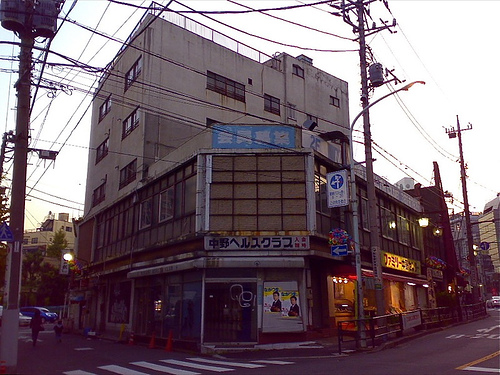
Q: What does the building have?
A: Many windows.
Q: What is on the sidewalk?
A: Light pole.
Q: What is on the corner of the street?
A: Store.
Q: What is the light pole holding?
A: Electrical wires.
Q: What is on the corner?
A: Old building.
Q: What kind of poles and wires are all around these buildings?
A: Electrical poles and wires.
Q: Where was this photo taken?
A: On a street corner.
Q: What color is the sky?
A: White.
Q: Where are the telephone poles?
A: In front of the building.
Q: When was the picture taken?
A: Daytime.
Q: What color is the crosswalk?
A: White.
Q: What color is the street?
A: Black.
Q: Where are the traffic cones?
A: Next to the building.